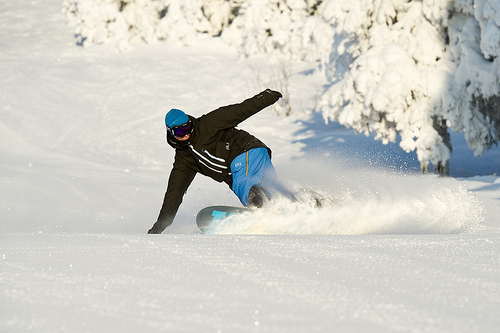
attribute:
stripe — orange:
[243, 150, 248, 175]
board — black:
[190, 196, 351, 232]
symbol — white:
[232, 159, 244, 168]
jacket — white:
[130, 52, 270, 174]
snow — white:
[2, 0, 498, 330]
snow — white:
[399, 125, 429, 161]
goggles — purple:
[169, 122, 194, 137]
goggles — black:
[162, 114, 216, 159]